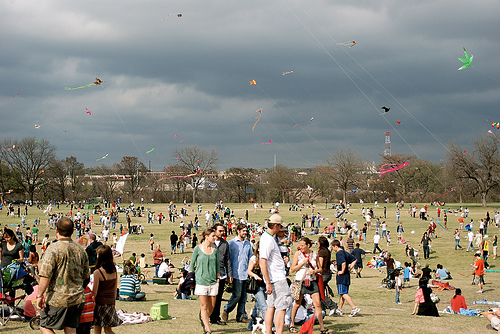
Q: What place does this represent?
A: It represents the park.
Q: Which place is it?
A: It is a park.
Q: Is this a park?
A: Yes, it is a park.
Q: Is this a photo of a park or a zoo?
A: It is showing a park.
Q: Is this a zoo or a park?
A: It is a park.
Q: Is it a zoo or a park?
A: It is a park.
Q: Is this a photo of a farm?
A: No, the picture is showing a park.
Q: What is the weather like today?
A: It is cloudy.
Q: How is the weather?
A: It is cloudy.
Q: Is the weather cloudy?
A: Yes, it is cloudy.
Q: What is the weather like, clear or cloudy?
A: It is cloudy.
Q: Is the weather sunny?
A: No, it is cloudy.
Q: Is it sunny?
A: No, it is cloudy.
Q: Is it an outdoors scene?
A: Yes, it is outdoors.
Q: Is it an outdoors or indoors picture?
A: It is outdoors.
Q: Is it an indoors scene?
A: No, it is outdoors.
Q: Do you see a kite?
A: Yes, there is a kite.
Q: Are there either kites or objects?
A: Yes, there is a kite.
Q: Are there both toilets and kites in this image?
A: No, there is a kite but no toilets.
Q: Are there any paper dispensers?
A: No, there are no paper dispensers.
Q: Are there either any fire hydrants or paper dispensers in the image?
A: No, there are no paper dispensers or fire hydrants.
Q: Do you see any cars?
A: No, there are no cars.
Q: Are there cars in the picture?
A: No, there are no cars.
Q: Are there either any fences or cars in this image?
A: No, there are no cars or fences.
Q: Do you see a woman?
A: Yes, there is a woman.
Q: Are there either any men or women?
A: Yes, there is a woman.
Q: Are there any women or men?
A: Yes, there is a woman.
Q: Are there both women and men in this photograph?
A: Yes, there are both a woman and a man.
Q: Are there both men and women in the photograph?
A: Yes, there are both a woman and a man.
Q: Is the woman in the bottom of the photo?
A: Yes, the woman is in the bottom of the image.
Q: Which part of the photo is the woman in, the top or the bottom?
A: The woman is in the bottom of the image.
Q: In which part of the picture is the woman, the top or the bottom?
A: The woman is in the bottom of the image.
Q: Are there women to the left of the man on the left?
A: Yes, there is a woman to the left of the man.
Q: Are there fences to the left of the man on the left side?
A: No, there is a woman to the left of the man.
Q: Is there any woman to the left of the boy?
A: Yes, there is a woman to the left of the boy.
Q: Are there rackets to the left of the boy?
A: No, there is a woman to the left of the boy.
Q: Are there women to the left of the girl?
A: Yes, there is a woman to the left of the girl.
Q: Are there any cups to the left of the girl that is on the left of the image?
A: No, there is a woman to the left of the girl.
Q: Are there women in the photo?
A: Yes, there is a woman.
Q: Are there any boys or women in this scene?
A: Yes, there is a woman.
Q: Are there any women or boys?
A: Yes, there is a woman.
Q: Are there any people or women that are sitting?
A: Yes, the woman is sitting.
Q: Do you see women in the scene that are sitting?
A: Yes, there is a woman that is sitting.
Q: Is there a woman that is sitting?
A: Yes, there is a woman that is sitting.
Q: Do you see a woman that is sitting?
A: Yes, there is a woman that is sitting.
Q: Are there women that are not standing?
A: Yes, there is a woman that is sitting.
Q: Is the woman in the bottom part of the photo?
A: Yes, the woman is in the bottom of the image.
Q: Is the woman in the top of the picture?
A: No, the woman is in the bottom of the image.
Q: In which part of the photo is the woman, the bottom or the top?
A: The woman is in the bottom of the image.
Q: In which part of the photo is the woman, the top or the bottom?
A: The woman is in the bottom of the image.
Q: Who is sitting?
A: The woman is sitting.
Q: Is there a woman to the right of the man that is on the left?
A: Yes, there is a woman to the right of the man.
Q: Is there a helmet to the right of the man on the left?
A: No, there is a woman to the right of the man.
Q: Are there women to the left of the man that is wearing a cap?
A: Yes, there is a woman to the left of the man.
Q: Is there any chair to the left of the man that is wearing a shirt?
A: No, there is a woman to the left of the man.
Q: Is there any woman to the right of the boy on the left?
A: Yes, there is a woman to the right of the boy.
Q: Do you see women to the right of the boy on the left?
A: Yes, there is a woman to the right of the boy.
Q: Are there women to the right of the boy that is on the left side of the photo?
A: Yes, there is a woman to the right of the boy.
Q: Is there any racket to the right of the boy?
A: No, there is a woman to the right of the boy.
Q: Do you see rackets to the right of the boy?
A: No, there is a woman to the right of the boy.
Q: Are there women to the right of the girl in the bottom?
A: Yes, there is a woman to the right of the girl.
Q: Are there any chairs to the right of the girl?
A: No, there is a woman to the right of the girl.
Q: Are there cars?
A: No, there are no cars.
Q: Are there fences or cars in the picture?
A: No, there are no cars or fences.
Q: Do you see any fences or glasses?
A: No, there are no fences or glasses.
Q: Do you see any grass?
A: Yes, there is grass.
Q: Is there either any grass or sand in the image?
A: Yes, there is grass.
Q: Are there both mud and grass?
A: No, there is grass but no mud.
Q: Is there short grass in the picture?
A: Yes, there is short grass.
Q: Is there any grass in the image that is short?
A: Yes, there is grass that is short.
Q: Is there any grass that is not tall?
A: Yes, there is short grass.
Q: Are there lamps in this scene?
A: No, there are no lamps.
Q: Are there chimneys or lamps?
A: No, there are no lamps or chimneys.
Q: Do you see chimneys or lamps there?
A: No, there are no lamps or chimneys.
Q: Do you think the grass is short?
A: Yes, the grass is short.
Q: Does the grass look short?
A: Yes, the grass is short.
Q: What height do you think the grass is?
A: The grass is short.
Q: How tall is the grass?
A: The grass is short.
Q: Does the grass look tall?
A: No, the grass is short.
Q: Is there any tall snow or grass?
A: No, there is grass but it is short.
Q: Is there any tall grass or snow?
A: No, there is grass but it is short.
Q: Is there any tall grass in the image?
A: No, there is grass but it is short.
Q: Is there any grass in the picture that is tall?
A: No, there is grass but it is short.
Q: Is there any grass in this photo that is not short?
A: No, there is grass but it is short.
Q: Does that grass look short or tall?
A: The grass is short.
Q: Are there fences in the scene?
A: No, there are no fences.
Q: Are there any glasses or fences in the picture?
A: No, there are no fences or glasses.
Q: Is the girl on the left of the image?
A: Yes, the girl is on the left of the image.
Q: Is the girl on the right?
A: No, the girl is on the left of the image.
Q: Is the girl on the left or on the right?
A: The girl is on the left of the image.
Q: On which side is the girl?
A: The girl is on the left of the image.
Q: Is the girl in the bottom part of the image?
A: Yes, the girl is in the bottom of the image.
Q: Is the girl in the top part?
A: No, the girl is in the bottom of the image.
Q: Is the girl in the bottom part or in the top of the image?
A: The girl is in the bottom of the image.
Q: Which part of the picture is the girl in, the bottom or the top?
A: The girl is in the bottom of the image.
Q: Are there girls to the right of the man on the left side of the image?
A: Yes, there is a girl to the right of the man.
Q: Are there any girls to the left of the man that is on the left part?
A: No, the girl is to the right of the man.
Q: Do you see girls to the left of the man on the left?
A: No, the girl is to the right of the man.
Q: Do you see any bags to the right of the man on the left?
A: No, there is a girl to the right of the man.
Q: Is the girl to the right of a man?
A: Yes, the girl is to the right of a man.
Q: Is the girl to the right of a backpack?
A: No, the girl is to the right of a man.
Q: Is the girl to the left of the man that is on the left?
A: No, the girl is to the right of the man.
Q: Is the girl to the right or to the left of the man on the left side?
A: The girl is to the right of the man.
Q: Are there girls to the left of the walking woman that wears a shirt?
A: Yes, there is a girl to the left of the woman.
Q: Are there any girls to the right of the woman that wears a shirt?
A: No, the girl is to the left of the woman.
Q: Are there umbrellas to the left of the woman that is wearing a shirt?
A: No, there is a girl to the left of the woman.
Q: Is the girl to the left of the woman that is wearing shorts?
A: Yes, the girl is to the left of the woman.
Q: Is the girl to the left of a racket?
A: No, the girl is to the left of the woman.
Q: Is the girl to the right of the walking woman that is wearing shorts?
A: No, the girl is to the left of the woman.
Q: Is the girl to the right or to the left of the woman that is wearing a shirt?
A: The girl is to the left of the woman.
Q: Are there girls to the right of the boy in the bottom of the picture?
A: Yes, there is a girl to the right of the boy.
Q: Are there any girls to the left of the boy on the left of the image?
A: No, the girl is to the right of the boy.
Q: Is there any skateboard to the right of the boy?
A: No, there is a girl to the right of the boy.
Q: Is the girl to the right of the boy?
A: Yes, the girl is to the right of the boy.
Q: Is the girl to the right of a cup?
A: No, the girl is to the right of the boy.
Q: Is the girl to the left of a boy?
A: No, the girl is to the right of a boy.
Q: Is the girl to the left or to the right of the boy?
A: The girl is to the right of the boy.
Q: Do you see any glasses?
A: No, there are no glasses.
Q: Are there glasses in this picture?
A: No, there are no glasses.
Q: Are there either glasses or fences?
A: No, there are no glasses or fences.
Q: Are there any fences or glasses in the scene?
A: No, there are no fences or glasses.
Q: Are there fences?
A: No, there are no fences.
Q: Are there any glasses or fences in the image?
A: No, there are no fences or glasses.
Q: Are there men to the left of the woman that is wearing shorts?
A: Yes, there is a man to the left of the woman.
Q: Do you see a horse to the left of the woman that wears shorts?
A: No, there is a man to the left of the woman.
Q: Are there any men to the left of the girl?
A: Yes, there is a man to the left of the girl.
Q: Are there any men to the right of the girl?
A: No, the man is to the left of the girl.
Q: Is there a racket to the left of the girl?
A: No, there is a man to the left of the girl.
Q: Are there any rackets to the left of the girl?
A: No, there is a man to the left of the girl.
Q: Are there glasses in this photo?
A: No, there are no glasses.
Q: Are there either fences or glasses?
A: No, there are no glasses or fences.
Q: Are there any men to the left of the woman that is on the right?
A: Yes, there is a man to the left of the woman.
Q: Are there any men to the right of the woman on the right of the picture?
A: No, the man is to the left of the woman.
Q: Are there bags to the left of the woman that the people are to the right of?
A: No, there is a man to the left of the woman.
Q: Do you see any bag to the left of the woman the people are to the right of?
A: No, there is a man to the left of the woman.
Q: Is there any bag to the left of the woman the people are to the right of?
A: No, there is a man to the left of the woman.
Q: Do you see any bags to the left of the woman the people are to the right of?
A: No, there is a man to the left of the woman.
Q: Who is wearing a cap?
A: The man is wearing a cap.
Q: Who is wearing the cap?
A: The man is wearing a cap.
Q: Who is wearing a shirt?
A: The man is wearing a shirt.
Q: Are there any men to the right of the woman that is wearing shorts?
A: Yes, there is a man to the right of the woman.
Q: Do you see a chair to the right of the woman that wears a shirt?
A: No, there is a man to the right of the woman.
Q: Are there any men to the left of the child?
A: Yes, there is a man to the left of the child.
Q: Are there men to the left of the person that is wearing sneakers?
A: Yes, there is a man to the left of the child.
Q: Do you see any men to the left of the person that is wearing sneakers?
A: Yes, there is a man to the left of the child.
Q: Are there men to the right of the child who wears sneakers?
A: No, the man is to the left of the kid.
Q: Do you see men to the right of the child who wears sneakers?
A: No, the man is to the left of the kid.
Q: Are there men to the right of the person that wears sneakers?
A: No, the man is to the left of the kid.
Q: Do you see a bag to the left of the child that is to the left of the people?
A: No, there is a man to the left of the kid.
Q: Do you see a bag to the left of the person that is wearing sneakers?
A: No, there is a man to the left of the kid.